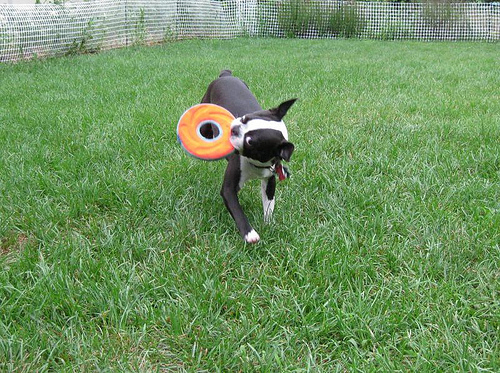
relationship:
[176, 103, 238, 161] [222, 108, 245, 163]
disc in mouth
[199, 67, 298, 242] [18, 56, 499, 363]
boston terrier standing on grass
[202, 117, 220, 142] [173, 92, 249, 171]
hole in frisbee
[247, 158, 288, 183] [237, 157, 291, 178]
collar around neck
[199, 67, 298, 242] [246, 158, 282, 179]
boston terrier wearing collar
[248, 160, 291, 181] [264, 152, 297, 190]
collar on collar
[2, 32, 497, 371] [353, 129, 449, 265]
grass in yard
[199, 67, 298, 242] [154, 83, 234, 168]
boston terrier enjoys playing with ring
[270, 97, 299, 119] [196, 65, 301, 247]
black ear on dog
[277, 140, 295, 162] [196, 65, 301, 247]
black ear on dog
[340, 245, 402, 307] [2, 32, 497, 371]
part on grass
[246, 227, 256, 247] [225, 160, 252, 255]
tip on leg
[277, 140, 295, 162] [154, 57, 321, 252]
black ear on dog